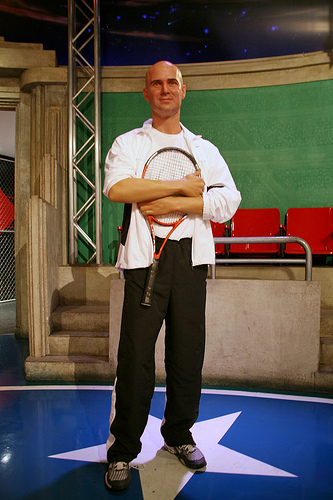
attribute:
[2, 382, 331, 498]
floor — shiny, blue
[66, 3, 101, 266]
tower — silver, metal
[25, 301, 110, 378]
steps — stone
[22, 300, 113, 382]
steps — stone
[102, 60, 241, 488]
he — staring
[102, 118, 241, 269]
zipper shirt — white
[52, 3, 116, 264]
structure — tall, metal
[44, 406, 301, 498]
star — white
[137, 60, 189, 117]
head — bald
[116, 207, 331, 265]
chairs — red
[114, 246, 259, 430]
sweatpants — black, white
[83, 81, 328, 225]
wall — green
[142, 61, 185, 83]
head — bald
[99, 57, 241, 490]
man — bald